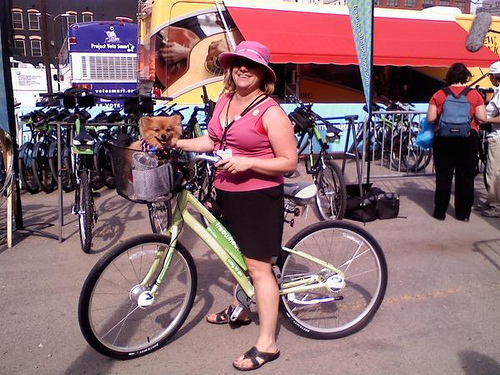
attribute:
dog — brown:
[126, 112, 181, 166]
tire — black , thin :
[72, 229, 202, 365]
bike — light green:
[72, 131, 392, 363]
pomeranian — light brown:
[124, 110, 182, 170]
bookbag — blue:
[433, 93, 474, 143]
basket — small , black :
[102, 139, 210, 209]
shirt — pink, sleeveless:
[209, 88, 290, 192]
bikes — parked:
[2, 81, 427, 247]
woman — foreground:
[190, 39, 327, 374]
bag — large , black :
[346, 181, 409, 226]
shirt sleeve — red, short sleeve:
[421, 83, 492, 138]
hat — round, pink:
[219, 38, 276, 89]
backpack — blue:
[437, 86, 477, 136]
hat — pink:
[207, 32, 278, 82]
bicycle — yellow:
[69, 154, 392, 362]